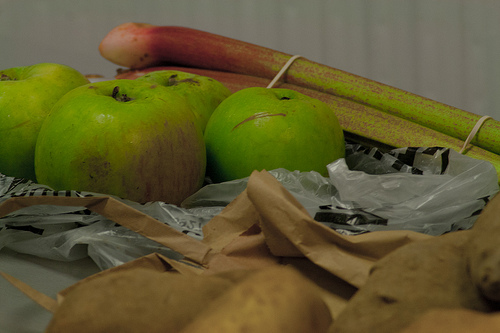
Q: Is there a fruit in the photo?
A: Yes, there is a fruit.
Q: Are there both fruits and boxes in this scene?
A: No, there is a fruit but no boxes.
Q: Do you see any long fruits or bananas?
A: Yes, there is a long fruit.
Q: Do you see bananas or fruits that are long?
A: Yes, the fruit is long.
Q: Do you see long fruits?
A: Yes, there is a long fruit.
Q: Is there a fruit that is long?
A: Yes, there is a fruit that is long.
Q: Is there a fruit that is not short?
A: Yes, there is a long fruit.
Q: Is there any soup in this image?
A: No, there is no soup.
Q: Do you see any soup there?
A: No, there is no soup.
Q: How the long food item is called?
A: The food item is a fruit.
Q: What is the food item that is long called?
A: The food item is a fruit.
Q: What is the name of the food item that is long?
A: The food item is a fruit.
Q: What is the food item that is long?
A: The food item is a fruit.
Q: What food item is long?
A: The food item is a fruit.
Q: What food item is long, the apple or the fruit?
A: The fruit is long.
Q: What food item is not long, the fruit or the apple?
A: The apple is not long.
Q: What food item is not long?
A: The food item is an apple.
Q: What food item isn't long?
A: The food item is an apple.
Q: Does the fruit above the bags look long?
A: Yes, the fruit is long.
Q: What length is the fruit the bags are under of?
A: The fruit is long.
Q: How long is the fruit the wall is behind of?
A: The fruit is long.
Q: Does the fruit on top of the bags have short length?
A: No, the fruit is long.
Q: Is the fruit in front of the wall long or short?
A: The fruit is long.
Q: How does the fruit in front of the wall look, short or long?
A: The fruit is long.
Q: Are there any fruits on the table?
A: Yes, there is a fruit on the table.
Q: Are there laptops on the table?
A: No, there is a fruit on the table.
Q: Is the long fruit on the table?
A: Yes, the fruit is on the table.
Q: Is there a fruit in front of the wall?
A: Yes, there is a fruit in front of the wall.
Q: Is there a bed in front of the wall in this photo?
A: No, there is a fruit in front of the wall.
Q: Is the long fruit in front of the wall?
A: Yes, the fruit is in front of the wall.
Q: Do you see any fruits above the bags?
A: Yes, there is a fruit above the bags.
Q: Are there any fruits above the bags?
A: Yes, there is a fruit above the bags.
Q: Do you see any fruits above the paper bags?
A: Yes, there is a fruit above the bags.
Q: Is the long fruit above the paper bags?
A: Yes, the fruit is above the bags.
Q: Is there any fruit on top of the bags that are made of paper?
A: Yes, there is a fruit on top of the bags.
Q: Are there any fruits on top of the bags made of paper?
A: Yes, there is a fruit on top of the bags.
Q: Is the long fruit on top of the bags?
A: Yes, the fruit is on top of the bags.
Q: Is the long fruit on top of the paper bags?
A: Yes, the fruit is on top of the bags.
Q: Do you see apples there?
A: Yes, there is an apple.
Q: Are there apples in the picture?
A: Yes, there is an apple.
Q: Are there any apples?
A: Yes, there is an apple.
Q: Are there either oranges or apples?
A: Yes, there is an apple.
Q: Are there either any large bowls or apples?
A: Yes, there is a large apple.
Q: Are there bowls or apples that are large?
A: Yes, the apple is large.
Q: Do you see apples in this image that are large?
A: Yes, there is a large apple.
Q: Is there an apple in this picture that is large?
A: Yes, there is an apple that is large.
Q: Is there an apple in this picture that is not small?
A: Yes, there is a large apple.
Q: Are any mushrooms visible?
A: No, there are no mushrooms.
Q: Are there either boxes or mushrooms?
A: No, there are no mushrooms or boxes.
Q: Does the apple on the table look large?
A: Yes, the apple is large.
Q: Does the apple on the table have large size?
A: Yes, the apple is large.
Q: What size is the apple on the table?
A: The apple is large.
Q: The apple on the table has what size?
A: The apple is large.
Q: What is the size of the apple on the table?
A: The apple is large.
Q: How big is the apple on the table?
A: The apple is large.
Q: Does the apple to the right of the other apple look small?
A: No, the apple is large.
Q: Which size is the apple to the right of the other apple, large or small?
A: The apple is large.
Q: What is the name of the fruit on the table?
A: The fruit is an apple.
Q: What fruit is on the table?
A: The fruit is an apple.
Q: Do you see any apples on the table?
A: Yes, there is an apple on the table.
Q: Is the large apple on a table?
A: Yes, the apple is on a table.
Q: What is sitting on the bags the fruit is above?
A: The apple is sitting on the bags.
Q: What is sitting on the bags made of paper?
A: The apple is sitting on the bags.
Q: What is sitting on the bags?
A: The apple is sitting on the bags.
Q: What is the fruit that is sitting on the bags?
A: The fruit is an apple.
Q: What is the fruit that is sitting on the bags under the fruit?
A: The fruit is an apple.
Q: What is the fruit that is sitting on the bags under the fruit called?
A: The fruit is an apple.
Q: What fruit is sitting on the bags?
A: The fruit is an apple.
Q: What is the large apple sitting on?
A: The apple is sitting on the bags.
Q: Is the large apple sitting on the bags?
A: Yes, the apple is sitting on the bags.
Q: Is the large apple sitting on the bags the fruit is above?
A: Yes, the apple is sitting on the bags.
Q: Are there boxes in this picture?
A: No, there are no boxes.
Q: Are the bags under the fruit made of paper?
A: Yes, the bags are made of paper.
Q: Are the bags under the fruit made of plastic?
A: No, the bags are made of paper.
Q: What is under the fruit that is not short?
A: The bags are under the fruit.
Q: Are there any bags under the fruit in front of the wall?
A: Yes, there are bags under the fruit.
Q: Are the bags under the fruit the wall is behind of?
A: Yes, the bags are under the fruit.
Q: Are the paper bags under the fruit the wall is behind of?
A: Yes, the bags are under the fruit.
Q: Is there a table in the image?
A: Yes, there is a table.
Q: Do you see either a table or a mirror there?
A: Yes, there is a table.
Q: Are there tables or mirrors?
A: Yes, there is a table.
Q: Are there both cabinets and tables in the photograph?
A: No, there is a table but no cabinets.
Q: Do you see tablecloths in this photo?
A: No, there are no tablecloths.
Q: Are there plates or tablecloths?
A: No, there are no tablecloths or plates.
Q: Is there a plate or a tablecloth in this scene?
A: No, there are no tablecloths or plates.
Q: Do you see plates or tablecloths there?
A: No, there are no tablecloths or plates.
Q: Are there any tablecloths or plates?
A: No, there are no tablecloths or plates.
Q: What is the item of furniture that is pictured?
A: The piece of furniture is a table.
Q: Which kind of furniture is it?
A: The piece of furniture is a table.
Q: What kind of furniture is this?
A: This is a table.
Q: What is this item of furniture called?
A: This is a table.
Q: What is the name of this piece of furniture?
A: This is a table.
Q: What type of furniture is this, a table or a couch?
A: This is a table.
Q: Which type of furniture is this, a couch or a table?
A: This is a table.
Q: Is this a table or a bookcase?
A: This is a table.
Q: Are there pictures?
A: No, there are no pictures.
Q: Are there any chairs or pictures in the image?
A: No, there are no pictures or chairs.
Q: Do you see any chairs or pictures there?
A: No, there are no pictures or chairs.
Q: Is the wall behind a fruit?
A: Yes, the wall is behind a fruit.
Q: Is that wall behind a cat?
A: No, the wall is behind a fruit.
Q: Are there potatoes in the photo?
A: Yes, there is a potato.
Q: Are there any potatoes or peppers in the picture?
A: Yes, there is a potato.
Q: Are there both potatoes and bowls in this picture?
A: No, there is a potato but no bowls.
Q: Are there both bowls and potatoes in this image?
A: No, there is a potato but no bowls.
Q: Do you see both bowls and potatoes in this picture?
A: No, there is a potato but no bowls.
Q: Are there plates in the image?
A: No, there are no plates.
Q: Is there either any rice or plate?
A: No, there are no plates or rice.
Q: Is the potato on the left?
A: Yes, the potato is on the left of the image.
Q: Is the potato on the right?
A: No, the potato is on the left of the image.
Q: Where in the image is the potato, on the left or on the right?
A: The potato is on the left of the image.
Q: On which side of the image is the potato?
A: The potato is on the left of the image.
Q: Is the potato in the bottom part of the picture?
A: Yes, the potato is in the bottom of the image.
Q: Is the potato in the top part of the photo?
A: No, the potato is in the bottom of the image.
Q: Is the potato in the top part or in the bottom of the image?
A: The potato is in the bottom of the image.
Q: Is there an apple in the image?
A: Yes, there is an apple.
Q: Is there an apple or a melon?
A: Yes, there is an apple.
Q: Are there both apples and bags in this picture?
A: Yes, there are both an apple and a bag.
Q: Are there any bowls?
A: No, there are no bowls.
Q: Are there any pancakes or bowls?
A: No, there are no bowls or pancakes.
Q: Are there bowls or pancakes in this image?
A: No, there are no bowls or pancakes.